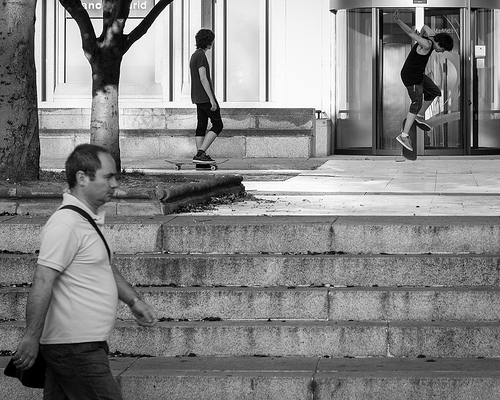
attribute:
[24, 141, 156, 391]
man — walking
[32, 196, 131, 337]
shirt — light colored, white, polo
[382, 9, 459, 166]
boy — jumping, jumping off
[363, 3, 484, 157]
door — revolving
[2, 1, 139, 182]
trees — growing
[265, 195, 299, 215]
dirt — spilling over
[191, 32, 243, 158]
boy — standing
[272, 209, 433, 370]
stairs — concrete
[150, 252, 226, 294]
markings — blurred, dark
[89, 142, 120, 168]
hairline — receding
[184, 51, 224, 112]
t-shirt — dark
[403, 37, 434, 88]
tank top — black